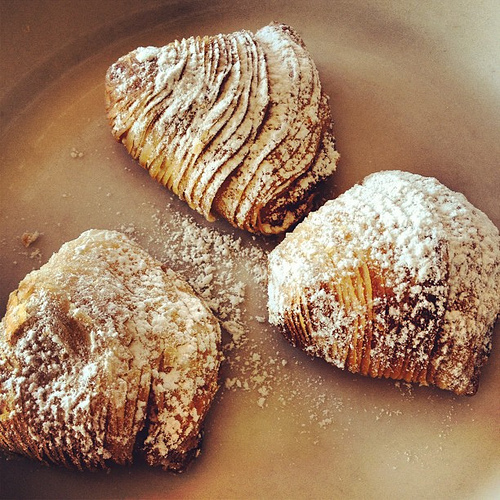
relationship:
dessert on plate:
[101, 20, 337, 239] [0, 2, 500, 499]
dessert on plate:
[262, 166, 499, 395] [0, 2, 500, 499]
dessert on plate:
[0, 225, 225, 476] [0, 2, 500, 499]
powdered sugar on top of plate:
[143, 200, 330, 427] [0, 2, 500, 499]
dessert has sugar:
[101, 20, 337, 239] [144, 27, 302, 209]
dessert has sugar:
[262, 166, 499, 395] [295, 174, 448, 354]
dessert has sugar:
[0, 225, 225, 476] [144, 27, 302, 209]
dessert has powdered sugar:
[101, 20, 337, 239] [144, 27, 302, 209]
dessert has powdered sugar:
[262, 166, 499, 395] [487, 353, 488, 354]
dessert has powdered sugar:
[0, 225, 225, 476] [23, 264, 186, 433]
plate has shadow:
[0, 2, 500, 499] [0, 0, 202, 145]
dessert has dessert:
[101, 20, 337, 239] [104, 20, 341, 235]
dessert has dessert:
[262, 166, 499, 395] [266, 168, 499, 396]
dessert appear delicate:
[101, 20, 337, 239] [8, 10, 498, 473]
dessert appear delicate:
[262, 166, 499, 395] [8, 10, 498, 473]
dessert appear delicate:
[0, 225, 225, 476] [8, 10, 498, 473]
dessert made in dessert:
[101, 20, 337, 239] [104, 20, 341, 235]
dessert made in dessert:
[262, 166, 499, 395] [266, 168, 499, 396]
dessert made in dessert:
[0, 225, 225, 476] [0, 228, 225, 476]